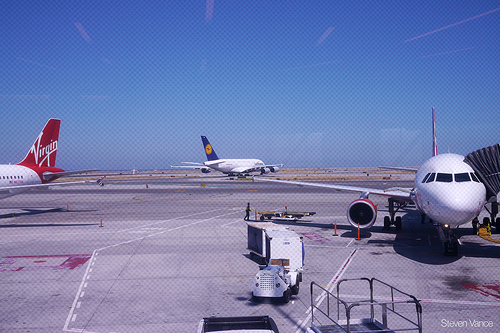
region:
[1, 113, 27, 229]
the plane is white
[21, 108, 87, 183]
the plane's tail is red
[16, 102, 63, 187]
the plane's tail says virgin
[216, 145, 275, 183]
the plane is white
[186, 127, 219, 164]
the plane's tail is blue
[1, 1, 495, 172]
the sky is blue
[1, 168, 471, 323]
the pavement is gray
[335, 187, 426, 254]
the plane's engine is red and white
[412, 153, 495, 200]
6 windows are on plane's front end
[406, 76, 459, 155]
plane's tail is red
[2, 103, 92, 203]
Virgin airlines logo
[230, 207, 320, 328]
luggage transportation on a tarmac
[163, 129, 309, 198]
a plane taxis on the tarmac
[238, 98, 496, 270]
an airplane loading or unloading passengers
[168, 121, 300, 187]
white airplane with a blue tail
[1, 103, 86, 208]
red and white tail of a plane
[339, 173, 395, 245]
an airplane engine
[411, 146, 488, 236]
the nose and cockpit of a plane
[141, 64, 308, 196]
a plane on a clear day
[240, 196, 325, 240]
an airport worker on the tarmac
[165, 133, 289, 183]
a taxiing airplane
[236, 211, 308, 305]
a moving luggage cart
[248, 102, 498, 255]
a parked airplane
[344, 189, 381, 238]
an airplane jet engine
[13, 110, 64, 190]
an airplane carrier logo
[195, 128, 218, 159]
an airplane carrier logo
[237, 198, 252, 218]
a person on the tarmac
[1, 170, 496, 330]
an airport tarmac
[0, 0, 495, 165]
a clear blue sky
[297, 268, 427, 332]
a truck with cargo hold on top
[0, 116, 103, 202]
The Tail of the 'virgin' airplane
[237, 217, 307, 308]
The long luggage truck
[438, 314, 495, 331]
The name of the photographer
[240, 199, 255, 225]
The person on the tarmac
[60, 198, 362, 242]
The cones on the tarmac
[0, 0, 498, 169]
The clear blue sky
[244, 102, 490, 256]
The plane with the terminal connected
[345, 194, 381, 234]
The engine of the plane connected to the terminal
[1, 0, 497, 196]
The reflection in the window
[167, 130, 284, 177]
The plane about to take off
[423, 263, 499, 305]
red paint and spill marks on the cement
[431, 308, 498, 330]
the name Steven Vance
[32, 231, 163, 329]
painted lines on the tarmac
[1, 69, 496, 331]
planes on the tarmac at an airport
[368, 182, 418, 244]
landing gear on an airplane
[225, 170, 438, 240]
wing and engine of an airplane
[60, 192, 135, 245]
orange directional markers on a tarmac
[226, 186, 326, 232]
worker walking beside a rolling platform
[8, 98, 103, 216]
red and white Virgin logo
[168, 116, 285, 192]
plane with a blue tail with gold circle